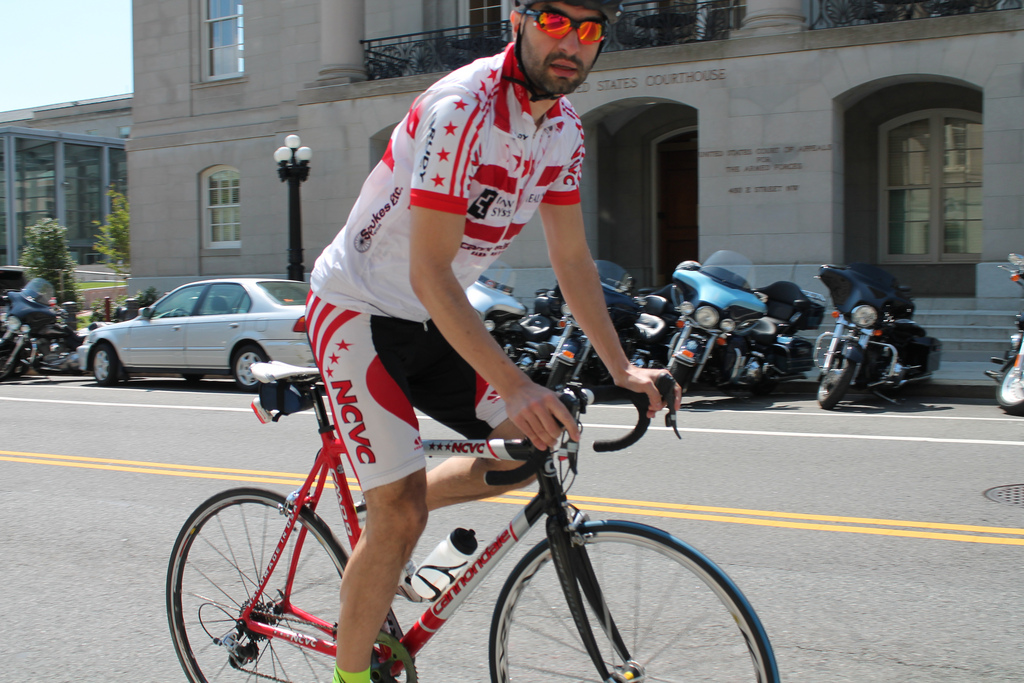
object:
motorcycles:
[657, 249, 945, 409]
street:
[0, 374, 1024, 683]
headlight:
[695, 305, 722, 328]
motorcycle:
[651, 250, 827, 406]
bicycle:
[162, 358, 773, 682]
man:
[306, 0, 686, 683]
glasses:
[506, 8, 612, 45]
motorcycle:
[811, 263, 943, 410]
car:
[76, 277, 364, 393]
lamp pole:
[273, 133, 312, 282]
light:
[295, 146, 312, 160]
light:
[285, 133, 301, 148]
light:
[273, 146, 293, 162]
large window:
[877, 107, 983, 264]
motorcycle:
[0, 276, 88, 382]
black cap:
[451, 527, 478, 555]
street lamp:
[298, 146, 314, 160]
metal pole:
[277, 160, 312, 282]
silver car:
[76, 277, 382, 392]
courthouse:
[129, 0, 1024, 390]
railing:
[354, 1, 746, 81]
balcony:
[358, 0, 750, 82]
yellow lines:
[0, 449, 1024, 548]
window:
[879, 106, 986, 265]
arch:
[829, 71, 985, 300]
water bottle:
[406, 526, 475, 602]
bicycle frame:
[299, 382, 557, 657]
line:
[0, 367, 1024, 683]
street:
[0, 370, 1021, 680]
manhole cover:
[981, 482, 1024, 510]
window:
[200, 163, 246, 249]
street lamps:
[273, 134, 312, 183]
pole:
[277, 160, 312, 282]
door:
[647, 124, 708, 290]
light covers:
[274, 134, 312, 162]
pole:
[269, 160, 316, 288]